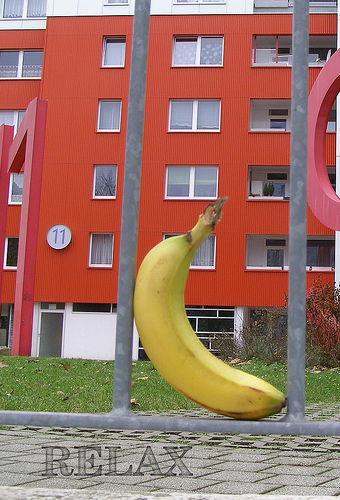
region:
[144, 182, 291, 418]
a yellow banana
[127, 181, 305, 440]
the banana is resting on the fence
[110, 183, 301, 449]
the banana is leaning against the bars of the fence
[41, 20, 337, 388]
the building is orange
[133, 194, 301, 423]
the banana is ripe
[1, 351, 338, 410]
the grass is green and covered with leaves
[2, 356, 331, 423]
there are leaves scattered throughout the lawn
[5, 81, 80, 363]
a large red sculpture of a number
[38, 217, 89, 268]
a circle with the number 11 in it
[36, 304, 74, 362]
a door with hazy glass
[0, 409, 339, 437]
long gray horizontal pole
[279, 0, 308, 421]
gray long vertical pole on the right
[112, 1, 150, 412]
gray long vertical pole on the left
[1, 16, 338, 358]
red building in the background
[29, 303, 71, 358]
white front door of the building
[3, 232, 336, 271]
first floor of windows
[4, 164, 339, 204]
windows on the second floor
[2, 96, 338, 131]
third floor of windows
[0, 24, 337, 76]
fourth floor windows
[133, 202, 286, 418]
big banana between two poles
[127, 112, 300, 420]
a banana on a metal fence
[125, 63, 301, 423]
the angle of the photograph makes the banana look huge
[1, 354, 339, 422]
a green grass lawn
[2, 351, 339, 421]
there are dry leaves scattered on the grass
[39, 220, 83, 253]
a circle with the number 11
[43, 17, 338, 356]
the building is bright orange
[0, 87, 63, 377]
a large number one sculpture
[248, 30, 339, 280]
open air balconies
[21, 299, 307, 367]
the bottom of the building is white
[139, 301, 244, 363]
lots of dark windows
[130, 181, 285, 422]
A banna in between the bars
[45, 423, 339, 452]
grass growind in the blocks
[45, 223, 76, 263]
the sign on the building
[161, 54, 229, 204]
the row of windows on the buiding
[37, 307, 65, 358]
the glass door of the building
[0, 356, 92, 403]
the leaves on the grass ground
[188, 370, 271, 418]
bruisies on the banana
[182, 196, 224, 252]
the stem of the banana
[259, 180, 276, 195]
the small bush on the balcony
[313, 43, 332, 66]
the satallite dish on the balcony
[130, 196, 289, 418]
banana propped up on a fence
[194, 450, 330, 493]
brick sidewalk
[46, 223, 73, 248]
number 11 in a circle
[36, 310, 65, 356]
door of the building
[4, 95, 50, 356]
red number 1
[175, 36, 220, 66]
patterned white curtains in the window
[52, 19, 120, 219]
reddish orange building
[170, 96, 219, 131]
white curtains in the window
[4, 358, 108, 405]
brown leaves in the green grass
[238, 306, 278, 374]
bushes growing in the grass